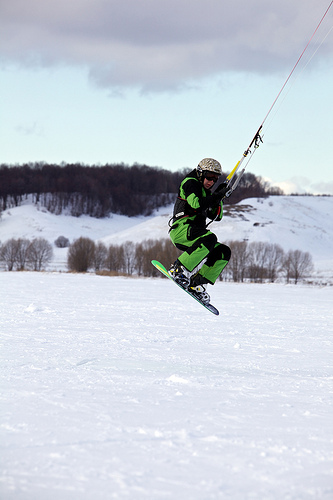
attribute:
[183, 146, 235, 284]
girl — flying, jumping, skiing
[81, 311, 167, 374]
snow — white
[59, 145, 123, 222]
trees — far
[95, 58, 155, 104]
sky — cloudy, dark, gray, blue